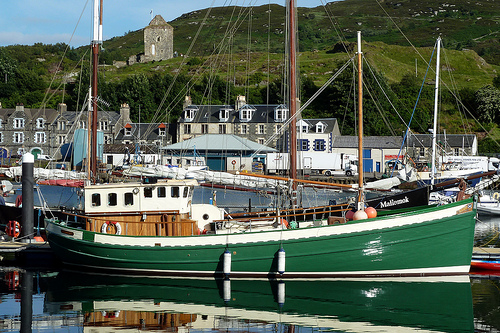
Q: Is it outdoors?
A: Yes, it is outdoors.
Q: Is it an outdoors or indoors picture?
A: It is outdoors.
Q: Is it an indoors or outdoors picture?
A: It is outdoors.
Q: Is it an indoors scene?
A: No, it is outdoors.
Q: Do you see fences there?
A: No, there are no fences.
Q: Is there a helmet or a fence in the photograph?
A: No, there are no fences or helmets.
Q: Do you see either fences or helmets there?
A: No, there are no fences or helmets.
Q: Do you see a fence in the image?
A: No, there are no fences.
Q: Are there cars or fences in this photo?
A: No, there are no fences or cars.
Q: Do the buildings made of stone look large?
A: Yes, the buildings are large.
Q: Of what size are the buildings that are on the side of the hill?
A: The buildings are large.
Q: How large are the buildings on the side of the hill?
A: The buildings are large.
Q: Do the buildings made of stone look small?
A: No, the buildings are large.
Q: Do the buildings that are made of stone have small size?
A: No, the buildings are large.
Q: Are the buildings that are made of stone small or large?
A: The buildings are large.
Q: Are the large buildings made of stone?
A: Yes, the buildings are made of stone.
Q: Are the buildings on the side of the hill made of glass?
A: No, the buildings are made of stone.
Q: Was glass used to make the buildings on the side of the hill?
A: No, the buildings are made of stone.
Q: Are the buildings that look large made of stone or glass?
A: The buildings are made of stone.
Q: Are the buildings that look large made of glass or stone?
A: The buildings are made of stone.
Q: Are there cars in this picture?
A: No, there are no cars.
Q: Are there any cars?
A: No, there are no cars.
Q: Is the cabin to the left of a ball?
A: Yes, the cabin is to the left of a ball.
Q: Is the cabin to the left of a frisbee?
A: No, the cabin is to the left of a ball.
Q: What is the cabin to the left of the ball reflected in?
A: The cabin is reflected in the water.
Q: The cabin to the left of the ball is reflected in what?
A: The cabin is reflected in the water.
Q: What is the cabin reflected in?
A: The cabin is reflected in the water.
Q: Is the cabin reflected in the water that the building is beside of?
A: Yes, the cabin is reflected in the water.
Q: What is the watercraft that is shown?
A: The watercraft is boats.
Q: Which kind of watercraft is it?
A: The watercraft is boats.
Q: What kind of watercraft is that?
A: These are boats.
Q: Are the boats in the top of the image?
A: No, the boats are in the bottom of the image.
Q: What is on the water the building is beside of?
A: The boats are on the water.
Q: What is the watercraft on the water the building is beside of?
A: The watercraft is boats.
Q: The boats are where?
A: The boats are on the water.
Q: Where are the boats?
A: The boats are on the water.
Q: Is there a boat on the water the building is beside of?
A: Yes, there are boats on the water.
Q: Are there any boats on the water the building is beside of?
A: Yes, there are boats on the water.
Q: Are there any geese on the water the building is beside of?
A: No, there are boats on the water.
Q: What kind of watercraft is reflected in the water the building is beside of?
A: The watercraft is boats.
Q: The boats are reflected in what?
A: The boats are reflected in the water.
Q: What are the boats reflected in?
A: The boats are reflected in the water.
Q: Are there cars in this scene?
A: No, there are no cars.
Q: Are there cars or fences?
A: No, there are no cars or fences.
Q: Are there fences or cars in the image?
A: No, there are no cars or fences.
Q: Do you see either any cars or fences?
A: No, there are no cars or fences.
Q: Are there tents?
A: No, there are no tents.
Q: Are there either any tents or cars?
A: No, there are no tents or cars.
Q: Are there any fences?
A: No, there are no fences.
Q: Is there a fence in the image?
A: No, there are no fences.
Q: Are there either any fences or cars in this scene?
A: No, there are no fences or cars.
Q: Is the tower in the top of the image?
A: Yes, the tower is in the top of the image.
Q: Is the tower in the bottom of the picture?
A: No, the tower is in the top of the image.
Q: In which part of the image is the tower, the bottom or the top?
A: The tower is in the top of the image.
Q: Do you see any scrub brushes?
A: No, there are no scrub brushes.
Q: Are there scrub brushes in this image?
A: No, there are no scrub brushes.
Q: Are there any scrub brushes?
A: No, there are no scrub brushes.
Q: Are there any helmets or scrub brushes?
A: No, there are no scrub brushes or helmets.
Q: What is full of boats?
A: The water is full of boats.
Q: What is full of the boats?
A: The water is full of boats.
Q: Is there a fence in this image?
A: No, there are no fences.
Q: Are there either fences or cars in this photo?
A: No, there are no fences or cars.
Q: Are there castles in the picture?
A: Yes, there is a castle.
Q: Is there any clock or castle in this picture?
A: Yes, there is a castle.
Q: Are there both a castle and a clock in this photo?
A: No, there is a castle but no clocks.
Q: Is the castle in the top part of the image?
A: Yes, the castle is in the top of the image.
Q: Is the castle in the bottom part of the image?
A: No, the castle is in the top of the image.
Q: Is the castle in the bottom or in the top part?
A: The castle is in the top of the image.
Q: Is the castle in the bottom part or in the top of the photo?
A: The castle is in the top of the image.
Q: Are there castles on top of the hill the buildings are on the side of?
A: Yes, there is a castle on top of the hill.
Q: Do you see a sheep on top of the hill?
A: No, there is a castle on top of the hill.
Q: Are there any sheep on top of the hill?
A: No, there is a castle on top of the hill.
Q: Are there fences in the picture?
A: No, there are no fences.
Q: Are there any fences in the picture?
A: No, there are no fences.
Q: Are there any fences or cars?
A: No, there are no fences or cars.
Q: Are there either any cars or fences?
A: No, there are no fences or cars.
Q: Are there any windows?
A: Yes, there are windows.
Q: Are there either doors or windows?
A: Yes, there are windows.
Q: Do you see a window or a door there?
A: Yes, there are windows.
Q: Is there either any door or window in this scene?
A: Yes, there are windows.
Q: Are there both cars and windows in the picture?
A: No, there are windows but no cars.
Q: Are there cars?
A: No, there are no cars.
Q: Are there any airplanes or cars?
A: No, there are no cars or airplanes.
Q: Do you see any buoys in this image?
A: Yes, there is a buoy.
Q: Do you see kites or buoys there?
A: Yes, there is a buoy.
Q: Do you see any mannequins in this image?
A: No, there are no mannequins.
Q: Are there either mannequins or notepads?
A: No, there are no mannequins or notepads.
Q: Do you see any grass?
A: Yes, there is grass.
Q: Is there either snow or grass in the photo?
A: Yes, there is grass.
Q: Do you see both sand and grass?
A: No, there is grass but no sand.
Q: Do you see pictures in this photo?
A: No, there are no pictures.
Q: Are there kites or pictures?
A: No, there are no pictures or kites.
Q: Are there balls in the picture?
A: Yes, there is a ball.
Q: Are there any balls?
A: Yes, there is a ball.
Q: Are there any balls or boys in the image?
A: Yes, there is a ball.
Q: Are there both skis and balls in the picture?
A: No, there is a ball but no skis.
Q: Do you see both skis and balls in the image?
A: No, there is a ball but no skis.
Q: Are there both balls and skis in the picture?
A: No, there is a ball but no skis.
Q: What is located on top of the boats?
A: The ball is on top of the boats.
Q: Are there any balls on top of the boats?
A: Yes, there is a ball on top of the boats.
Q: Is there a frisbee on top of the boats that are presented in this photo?
A: No, there is a ball on top of the boats.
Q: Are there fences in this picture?
A: No, there are no fences.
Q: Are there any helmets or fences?
A: No, there are no fences or helmets.